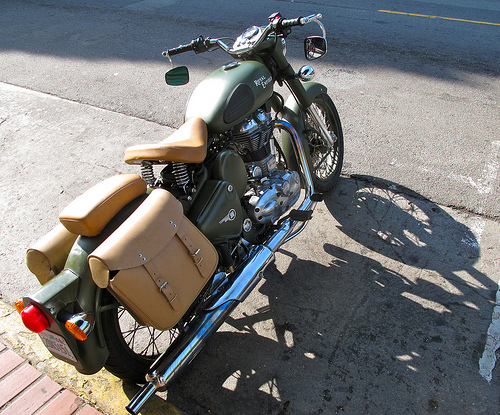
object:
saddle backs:
[23, 172, 220, 332]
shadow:
[0, 0, 499, 85]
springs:
[172, 162, 190, 186]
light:
[63, 311, 93, 342]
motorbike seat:
[123, 116, 208, 166]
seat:
[55, 173, 147, 238]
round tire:
[295, 91, 345, 192]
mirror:
[302, 19, 328, 62]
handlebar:
[160, 35, 206, 58]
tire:
[290, 93, 342, 200]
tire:
[98, 287, 185, 384]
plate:
[35, 327, 80, 363]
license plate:
[37, 329, 79, 363]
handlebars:
[281, 11, 323, 27]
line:
[377, 8, 500, 27]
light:
[230, 24, 287, 62]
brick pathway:
[0, 346, 107, 415]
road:
[0, 2, 500, 412]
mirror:
[160, 55, 189, 86]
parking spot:
[0, 81, 498, 413]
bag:
[85, 187, 219, 331]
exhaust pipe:
[124, 198, 314, 414]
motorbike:
[13, 11, 345, 414]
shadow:
[120, 172, 498, 415]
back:
[13, 280, 110, 376]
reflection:
[321, 173, 481, 272]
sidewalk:
[242, 180, 483, 402]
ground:
[279, 6, 500, 411]